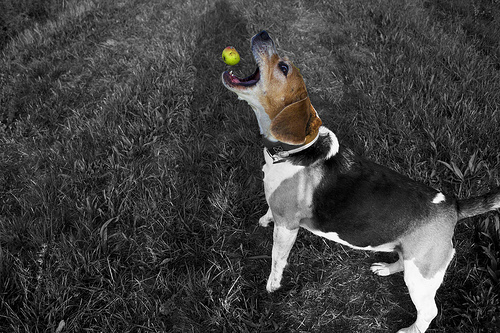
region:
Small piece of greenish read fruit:
[217, 45, 243, 70]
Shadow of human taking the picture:
[171, 1, 312, 303]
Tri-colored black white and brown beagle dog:
[212, 23, 499, 328]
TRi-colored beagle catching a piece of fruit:
[211, 24, 488, 331]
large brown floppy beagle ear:
[271, 95, 323, 148]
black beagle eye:
[271, 57, 296, 79]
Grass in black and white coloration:
[4, 9, 176, 329]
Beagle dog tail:
[448, 190, 498, 217]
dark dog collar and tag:
[257, 129, 307, 170]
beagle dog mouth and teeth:
[211, 27, 276, 101]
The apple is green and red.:
[219, 46, 240, 63]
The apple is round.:
[218, 43, 240, 65]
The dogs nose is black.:
[251, 28, 269, 43]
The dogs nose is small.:
[255, 28, 272, 43]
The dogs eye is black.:
[277, 58, 291, 81]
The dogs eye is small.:
[276, 61, 291, 74]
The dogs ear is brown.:
[271, 99, 311, 148]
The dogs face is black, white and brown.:
[220, 25, 320, 147]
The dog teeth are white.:
[223, 71, 236, 77]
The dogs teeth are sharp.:
[227, 71, 238, 78]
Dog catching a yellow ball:
[207, 23, 475, 317]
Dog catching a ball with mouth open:
[211, 25, 488, 331]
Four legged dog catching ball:
[216, 26, 476, 330]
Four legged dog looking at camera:
[210, 28, 485, 330]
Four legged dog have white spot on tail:
[195, 22, 465, 328]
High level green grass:
[56, 25, 186, 235]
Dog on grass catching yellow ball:
[125, 13, 496, 328]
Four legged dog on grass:
[210, 28, 495, 328]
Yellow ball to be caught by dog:
[210, 32, 243, 68]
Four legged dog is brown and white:
[197, 28, 491, 330]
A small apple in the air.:
[219, 46, 239, 66]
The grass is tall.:
[83, 62, 180, 238]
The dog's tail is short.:
[458, 186, 498, 226]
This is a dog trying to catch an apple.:
[206, 35, 499, 331]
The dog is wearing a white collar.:
[257, 141, 334, 158]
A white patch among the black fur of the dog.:
[425, 185, 449, 214]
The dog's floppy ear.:
[268, 99, 313, 149]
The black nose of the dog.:
[250, 29, 273, 45]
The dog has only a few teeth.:
[219, 70, 242, 85]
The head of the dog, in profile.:
[212, 32, 327, 152]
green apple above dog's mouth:
[217, 36, 247, 71]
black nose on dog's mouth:
[248, 14, 286, 59]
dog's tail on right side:
[452, 170, 496, 223]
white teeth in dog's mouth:
[220, 65, 242, 80]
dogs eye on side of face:
[261, 59, 306, 81]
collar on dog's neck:
[253, 137, 348, 174]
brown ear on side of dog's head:
[270, 92, 327, 164]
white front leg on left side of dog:
[274, 205, 316, 312]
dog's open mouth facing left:
[208, 21, 275, 99]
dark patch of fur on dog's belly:
[311, 191, 387, 262]